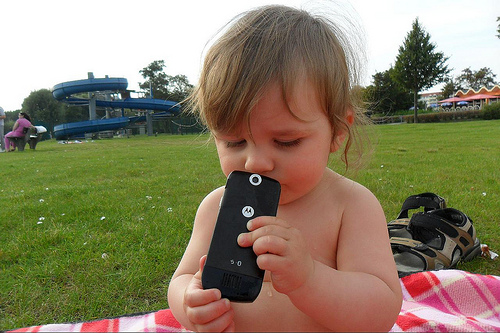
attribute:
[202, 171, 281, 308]
cell phone — black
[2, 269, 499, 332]
blanket — checkered, white, red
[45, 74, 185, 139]
slide — blue, enclosed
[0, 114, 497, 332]
grass — green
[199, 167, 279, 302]
cellphone — black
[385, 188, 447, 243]
sandal — tan, brown, black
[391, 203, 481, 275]
sandal — tan, brown, black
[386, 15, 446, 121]
tree — green, tall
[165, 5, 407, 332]
child — young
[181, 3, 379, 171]
hair — brown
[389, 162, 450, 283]
sandals — tan 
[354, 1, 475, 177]
tree — small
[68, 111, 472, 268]
grass — short , green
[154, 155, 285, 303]
phone — black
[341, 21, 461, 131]
leaves — green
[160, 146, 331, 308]
phone — black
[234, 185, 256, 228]
emblem — silver 